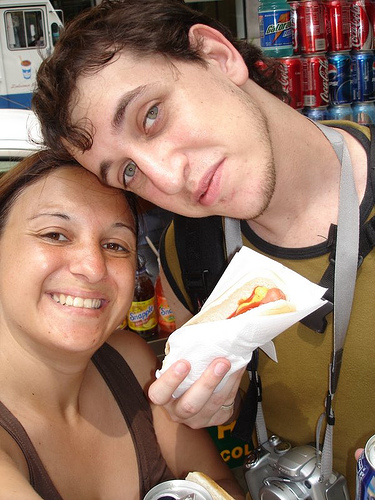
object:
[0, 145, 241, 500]
woman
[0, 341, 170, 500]
brown shirt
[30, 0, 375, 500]
man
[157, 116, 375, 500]
yellow shirt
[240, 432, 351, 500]
camera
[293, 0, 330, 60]
can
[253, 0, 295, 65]
bottles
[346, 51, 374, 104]
can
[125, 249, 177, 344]
bottles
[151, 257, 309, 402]
hotdog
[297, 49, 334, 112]
can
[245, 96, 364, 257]
man's neck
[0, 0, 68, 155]
truck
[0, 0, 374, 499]
couple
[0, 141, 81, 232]
hair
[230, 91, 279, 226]
facial hair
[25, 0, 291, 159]
brown hair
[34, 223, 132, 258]
brown eyes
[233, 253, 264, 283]
napkin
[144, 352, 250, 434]
hand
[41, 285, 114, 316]
smile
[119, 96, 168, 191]
eyes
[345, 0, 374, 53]
can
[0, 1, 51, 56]
side window